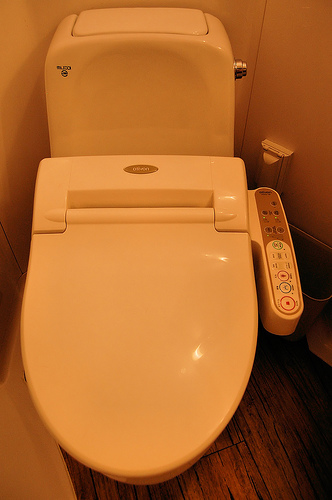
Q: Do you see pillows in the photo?
A: No, there are no pillows.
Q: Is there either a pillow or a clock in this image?
A: No, there are no pillows or clocks.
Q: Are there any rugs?
A: No, there are no rugs.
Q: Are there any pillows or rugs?
A: No, there are no rugs or pillows.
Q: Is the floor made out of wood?
A: Yes, the floor is made of wood.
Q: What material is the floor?
A: The floor is made of wood.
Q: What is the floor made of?
A: The floor is made of wood.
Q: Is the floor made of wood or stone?
A: The floor is made of wood.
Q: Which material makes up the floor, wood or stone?
A: The floor is made of wood.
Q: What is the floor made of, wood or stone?
A: The floor is made of wood.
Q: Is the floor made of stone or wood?
A: The floor is made of wood.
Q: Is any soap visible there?
A: No, there are no soaps.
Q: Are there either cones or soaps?
A: No, there are no soaps or cones.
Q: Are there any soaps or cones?
A: No, there are no soaps or cones.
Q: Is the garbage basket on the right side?
A: Yes, the garbage basket is on the right of the image.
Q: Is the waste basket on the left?
A: No, the waste basket is on the right of the image.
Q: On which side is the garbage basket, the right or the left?
A: The garbage basket is on the right of the image.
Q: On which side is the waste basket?
A: The waste basket is on the right of the image.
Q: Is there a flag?
A: No, there are no flags.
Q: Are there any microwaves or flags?
A: No, there are no flags or microwaves.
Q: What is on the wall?
A: The electrical outlet is on the wall.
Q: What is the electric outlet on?
A: The electric outlet is on the wall.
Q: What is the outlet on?
A: The electric outlet is on the wall.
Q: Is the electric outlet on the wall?
A: Yes, the electric outlet is on the wall.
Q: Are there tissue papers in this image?
A: No, there are no tissue papers.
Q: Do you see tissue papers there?
A: No, there are no tissue papers.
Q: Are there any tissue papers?
A: No, there are no tissue papers.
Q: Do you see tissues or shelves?
A: No, there are no tissues or shelves.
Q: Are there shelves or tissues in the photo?
A: No, there are no tissues or shelves.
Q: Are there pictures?
A: No, there are no pictures.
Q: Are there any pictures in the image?
A: No, there are no pictures.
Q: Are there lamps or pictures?
A: No, there are no pictures or lamps.